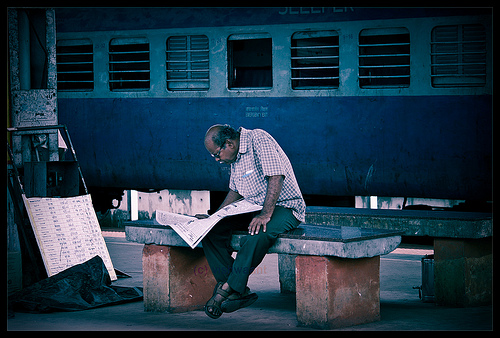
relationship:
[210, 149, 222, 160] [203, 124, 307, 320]
glasses on man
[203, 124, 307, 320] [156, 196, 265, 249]
man reading paper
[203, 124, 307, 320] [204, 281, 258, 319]
man wearing sandals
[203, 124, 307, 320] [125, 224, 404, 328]
man on bench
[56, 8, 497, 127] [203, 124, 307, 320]
train behind man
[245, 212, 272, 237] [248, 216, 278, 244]
hand on knee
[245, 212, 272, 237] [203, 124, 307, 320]
hand of man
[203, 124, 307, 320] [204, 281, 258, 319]
man crossed feet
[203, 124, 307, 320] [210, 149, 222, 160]
man wearing glasses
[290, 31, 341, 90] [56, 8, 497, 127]
window on train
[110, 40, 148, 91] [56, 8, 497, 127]
window on train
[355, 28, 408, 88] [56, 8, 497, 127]
window on train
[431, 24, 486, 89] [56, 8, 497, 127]
window on train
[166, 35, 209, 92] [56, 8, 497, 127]
window on train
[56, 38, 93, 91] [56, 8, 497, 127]
window on train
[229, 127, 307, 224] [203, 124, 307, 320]
shirt on man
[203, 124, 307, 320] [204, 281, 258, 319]
man has sandals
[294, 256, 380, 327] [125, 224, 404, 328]
leg of bench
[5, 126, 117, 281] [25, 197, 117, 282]
stand with paper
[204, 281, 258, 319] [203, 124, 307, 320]
sandals on man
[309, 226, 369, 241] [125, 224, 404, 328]
reflection on bench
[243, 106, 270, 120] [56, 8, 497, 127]
mark on train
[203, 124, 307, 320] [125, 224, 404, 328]
man n bench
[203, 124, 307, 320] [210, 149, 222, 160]
man with glasses